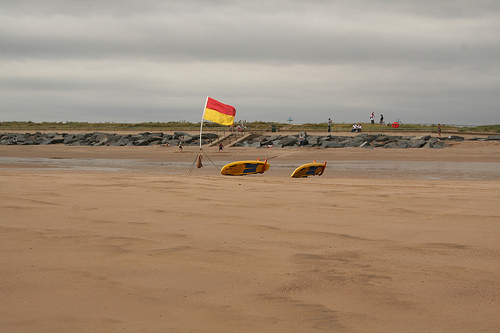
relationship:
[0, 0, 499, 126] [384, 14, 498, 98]
clouds in sky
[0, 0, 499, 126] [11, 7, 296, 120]
clouds in sky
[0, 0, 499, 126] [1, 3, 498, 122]
clouds in sky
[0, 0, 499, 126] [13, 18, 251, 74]
clouds in sky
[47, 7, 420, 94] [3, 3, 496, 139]
clouds in sky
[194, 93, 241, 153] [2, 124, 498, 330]
flag in sand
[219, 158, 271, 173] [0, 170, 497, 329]
surfboard in sand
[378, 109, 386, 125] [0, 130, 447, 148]
person sitting on rocks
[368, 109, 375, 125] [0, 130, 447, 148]
person sitting on rocks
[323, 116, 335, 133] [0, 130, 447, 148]
person sitting on rocks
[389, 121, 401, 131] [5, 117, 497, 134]
kite on ground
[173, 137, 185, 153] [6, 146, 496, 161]
person standing in sand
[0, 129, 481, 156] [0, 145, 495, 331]
rocks at edge sand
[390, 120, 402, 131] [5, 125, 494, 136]
cloth in sand